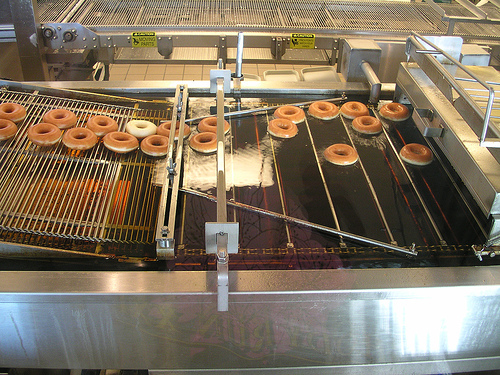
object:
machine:
[0, 0, 500, 82]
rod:
[204, 58, 239, 262]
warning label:
[131, 31, 157, 48]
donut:
[0, 102, 191, 156]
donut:
[267, 118, 298, 139]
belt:
[166, 84, 491, 262]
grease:
[0, 84, 499, 272]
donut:
[28, 122, 61, 146]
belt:
[0, 80, 190, 262]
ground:
[108, 63, 200, 79]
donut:
[189, 131, 217, 153]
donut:
[18, 81, 456, 217]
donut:
[308, 101, 339, 120]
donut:
[102, 131, 139, 153]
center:
[102, 131, 140, 157]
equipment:
[2, 0, 499, 375]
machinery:
[0, 29, 500, 317]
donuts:
[0, 101, 434, 166]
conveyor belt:
[0, 57, 500, 313]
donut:
[125, 120, 157, 139]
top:
[308, 101, 339, 118]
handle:
[412, 108, 443, 137]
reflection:
[0, 293, 499, 374]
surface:
[0, 284, 499, 374]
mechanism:
[393, 29, 500, 261]